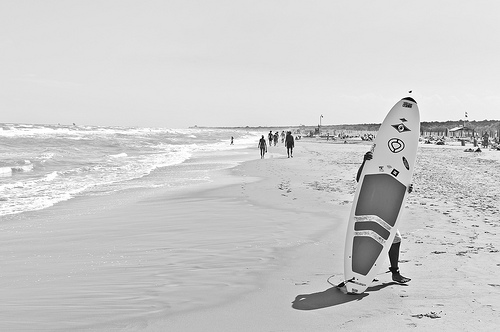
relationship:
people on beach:
[281, 131, 299, 160] [0, 125, 499, 331]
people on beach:
[256, 134, 270, 160] [0, 125, 499, 331]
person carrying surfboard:
[357, 143, 419, 291] [340, 87, 427, 301]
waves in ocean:
[5, 123, 219, 137] [1, 119, 267, 225]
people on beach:
[473, 146, 483, 156] [0, 125, 499, 331]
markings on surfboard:
[391, 120, 414, 134] [340, 87, 427, 301]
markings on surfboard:
[400, 114, 410, 122] [340, 87, 427, 301]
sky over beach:
[1, 1, 500, 133] [0, 125, 499, 331]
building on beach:
[449, 124, 478, 140] [0, 125, 499, 331]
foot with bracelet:
[385, 271, 410, 287] [388, 264, 403, 273]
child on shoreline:
[228, 132, 237, 149] [1, 113, 274, 295]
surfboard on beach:
[340, 87, 427, 301] [0, 125, 499, 331]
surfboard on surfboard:
[340, 89, 419, 301] [340, 87, 427, 301]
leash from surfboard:
[369, 265, 392, 281] [340, 87, 427, 301]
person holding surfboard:
[357, 143, 419, 291] [340, 87, 427, 301]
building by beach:
[449, 124, 478, 140] [0, 125, 499, 331]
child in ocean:
[228, 132, 237, 149] [1, 119, 267, 225]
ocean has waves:
[1, 119, 267, 225] [5, 123, 219, 137]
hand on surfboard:
[363, 150, 374, 161] [340, 87, 427, 301]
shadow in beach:
[288, 272, 374, 314] [0, 125, 499, 331]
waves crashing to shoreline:
[5, 123, 219, 137] [1, 113, 274, 295]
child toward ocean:
[228, 132, 237, 149] [1, 119, 267, 225]